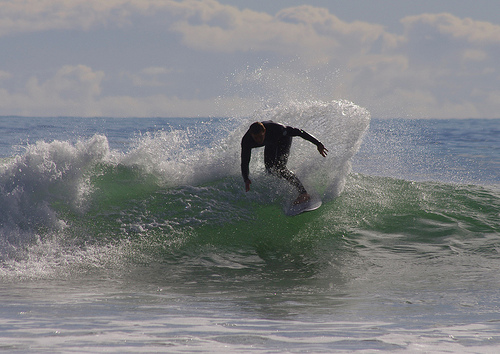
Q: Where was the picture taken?
A: In the water.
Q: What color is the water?
A: Blue.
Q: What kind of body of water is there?
A: An ocean.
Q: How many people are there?
A: One.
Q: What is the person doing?
A: Surfing.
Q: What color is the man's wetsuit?
A: Black.